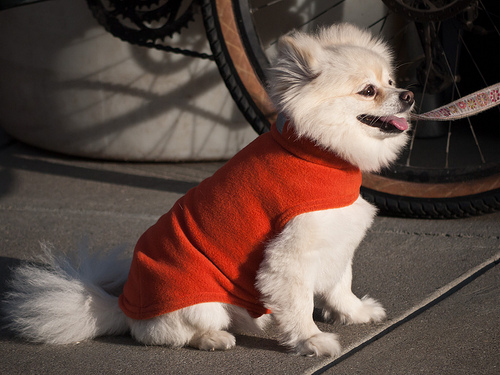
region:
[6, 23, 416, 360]
A small white dog in an orange sweater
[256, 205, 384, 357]
Front two white legs of a dog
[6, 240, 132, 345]
Puffy white dog tail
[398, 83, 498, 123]
Flowered leash going to the dog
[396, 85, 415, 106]
Small brown nose on a dogs face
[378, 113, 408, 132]
Pink tongue coming out of a dog's mouth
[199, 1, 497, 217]
Black and brown tire of a bike.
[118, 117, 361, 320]
Orange sweater on a dog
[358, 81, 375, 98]
A dog's right eye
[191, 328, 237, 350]
A dog's back right paw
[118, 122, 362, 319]
an orange doggie sweater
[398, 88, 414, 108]
the dog has a black nose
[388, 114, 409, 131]
the dogs pink tongue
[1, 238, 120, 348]
the dogs fluffy white tail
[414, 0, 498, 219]
a bicycles spoke wheel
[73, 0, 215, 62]
a bicycle chain and sprocket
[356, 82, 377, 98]
the dogs brown eye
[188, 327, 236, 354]
the dogs beige paw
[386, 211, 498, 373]
a grey cement floor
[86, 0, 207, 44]
the bicycles gear sprocket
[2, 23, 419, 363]
dog looks off into distance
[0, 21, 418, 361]
dog wears sweater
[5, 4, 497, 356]
dog sits next to bicycle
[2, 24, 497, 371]
dog sits on sidewalk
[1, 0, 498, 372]
bicycle is parked on sidewalk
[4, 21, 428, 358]
dog is well groomed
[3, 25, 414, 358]
dog is taking it easy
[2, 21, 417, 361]
sweater is on dog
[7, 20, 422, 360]
dog is inside sweater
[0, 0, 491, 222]
bicycle casts a shadow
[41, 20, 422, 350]
small white dog wearing a red sweater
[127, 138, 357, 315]
red fleece dog sweater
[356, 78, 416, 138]
dog with mouht open and tongue out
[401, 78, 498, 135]
dog's leash with a floral pattern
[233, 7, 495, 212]
bicycle wheel behind small dog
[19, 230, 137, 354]
small dog's furry tail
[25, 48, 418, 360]
dog sitting on sidewalk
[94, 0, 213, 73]
gears and chains of bicycle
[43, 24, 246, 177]
shadows on white building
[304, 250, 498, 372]
groove in sidewalk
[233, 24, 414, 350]
A small white dog wearing a red sweater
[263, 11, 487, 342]
A small white dog in a red sweater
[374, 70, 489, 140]
The dog is on a leash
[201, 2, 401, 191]
The white dog is standing near a bicycle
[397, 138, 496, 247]
The bicycle is parken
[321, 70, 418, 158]
The dog appears happy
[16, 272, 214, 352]
The white dog in the sweater has a bushy tail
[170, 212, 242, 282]
The sweater is red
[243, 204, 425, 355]
The white dog is standing on the sidewalk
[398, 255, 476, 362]
The cement is smooth and gray